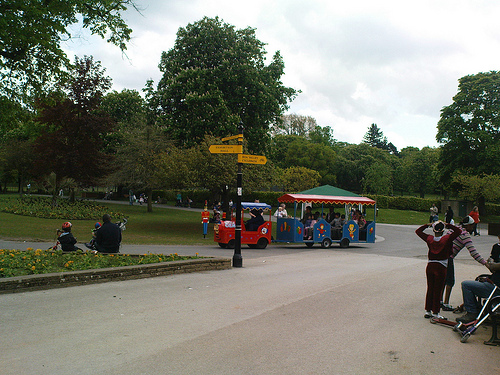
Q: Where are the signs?
A: On the pole.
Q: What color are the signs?
A: Yellow.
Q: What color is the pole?
A: Black.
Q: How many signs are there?
A: Three.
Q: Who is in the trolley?
A: The passengers.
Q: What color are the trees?
A: Green.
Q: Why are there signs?
A: To direct people.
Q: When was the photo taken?
A: Daytime.